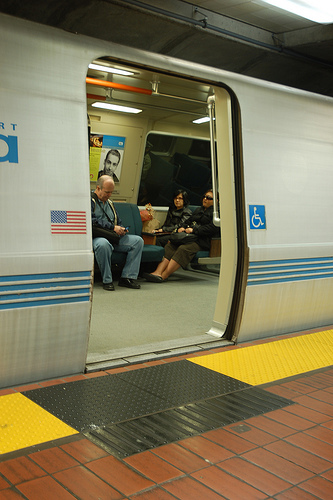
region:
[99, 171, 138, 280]
this is a man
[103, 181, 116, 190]
the man is light skinned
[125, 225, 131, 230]
this is a phone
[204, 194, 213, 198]
this is a spectacle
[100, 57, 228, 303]
this is a door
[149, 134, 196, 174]
this is a window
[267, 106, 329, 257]
this is a train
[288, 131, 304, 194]
the train is white in color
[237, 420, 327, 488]
this is the ground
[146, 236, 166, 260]
this is a chair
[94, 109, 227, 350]
the door is open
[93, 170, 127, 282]
this is a man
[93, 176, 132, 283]
the man is sitted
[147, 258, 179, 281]
the legs are crossed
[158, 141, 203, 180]
this is the window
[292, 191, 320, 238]
this is an electric train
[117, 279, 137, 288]
the shoe is black in color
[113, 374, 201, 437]
this is a mat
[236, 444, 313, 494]
the floor is tiled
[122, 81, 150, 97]
this is a poe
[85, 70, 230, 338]
People are inside a subway train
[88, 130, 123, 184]
A poster is in the background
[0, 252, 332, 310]
Train has a blue stripe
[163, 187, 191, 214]
Woman has dark colored hair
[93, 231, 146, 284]
Man is wearing blue jeans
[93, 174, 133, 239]
Man is looking at his phone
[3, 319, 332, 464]
A yellow line is on the ground floor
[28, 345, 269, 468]
A black stepping mat is on the ground floor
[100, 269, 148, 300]
Man is wearing black shoes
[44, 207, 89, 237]
American flag is on the side of the subway train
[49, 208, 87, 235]
an image of the American flag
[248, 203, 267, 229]
a blue handicapped sign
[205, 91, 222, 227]
a vertical handrail found inside a subway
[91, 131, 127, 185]
advertisement seen inside a subway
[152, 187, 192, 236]
a woman in glasses and a black jacket sitting on a subway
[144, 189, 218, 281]
a woman wearing sunglasses and relaxing while sitting inside a subway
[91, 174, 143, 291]
an older man wearing light blue jeans sitting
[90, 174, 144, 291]
a man sitting on a subway looking at his phone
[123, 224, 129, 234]
a black cell phone with a blue screen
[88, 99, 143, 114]
light fixture on the ceiling of a subway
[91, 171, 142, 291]
man using a cell phone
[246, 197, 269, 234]
blue sign with white pictograph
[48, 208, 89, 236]
decal of the american flag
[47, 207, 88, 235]
red and white striped flag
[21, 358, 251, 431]
metal plate with dimples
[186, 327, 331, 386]
yellow metal plate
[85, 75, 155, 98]
orange padding a hand rail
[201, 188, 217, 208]
woman wearing sunglasses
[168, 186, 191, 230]
woman with black hair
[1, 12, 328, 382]
grey train car with blue stripes